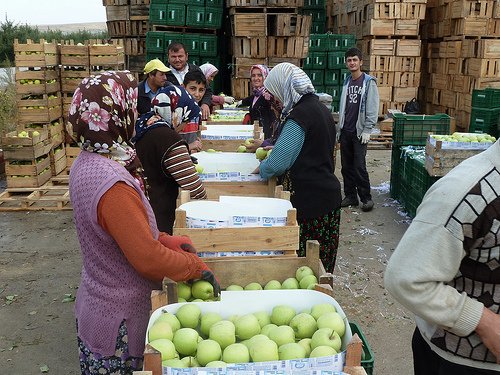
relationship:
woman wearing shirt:
[57, 0, 144, 370] [62, 178, 149, 336]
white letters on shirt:
[348, 82, 361, 103] [342, 76, 364, 130]